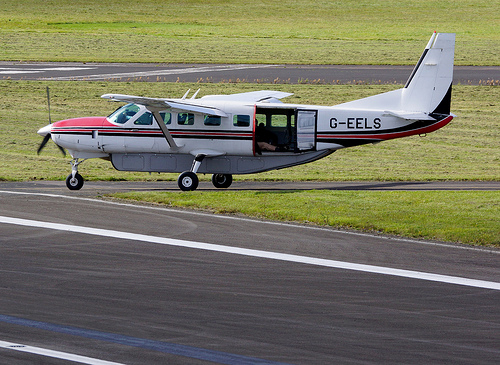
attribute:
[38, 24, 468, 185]
plane — white, daytime, landing, landed, local, taxiing, small, operating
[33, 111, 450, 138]
stripes — red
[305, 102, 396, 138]
letters — black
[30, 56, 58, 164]
propeller — stationary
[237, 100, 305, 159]
door — open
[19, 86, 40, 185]
field — green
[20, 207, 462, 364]
tarmac — grey, cement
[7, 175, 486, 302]
lines — white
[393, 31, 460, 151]
tail — white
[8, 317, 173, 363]
line — blue